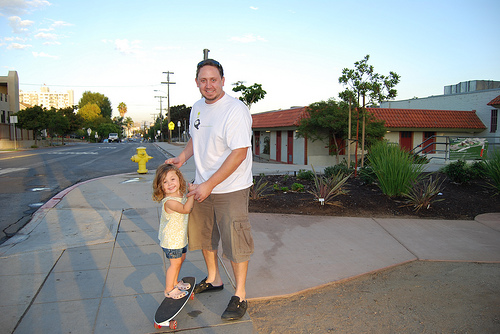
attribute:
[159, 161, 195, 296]
girl — little, standing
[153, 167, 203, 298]
girl — little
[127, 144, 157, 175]
fire hydrant — yellow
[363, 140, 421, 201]
plants — spike shaped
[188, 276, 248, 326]
shoes — black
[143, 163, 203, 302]
girl — little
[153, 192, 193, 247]
shirt — yellow, sleeveless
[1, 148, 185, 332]
sidewalk — sloped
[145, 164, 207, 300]
girl — little, standing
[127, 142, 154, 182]
hydrant — yellow, fire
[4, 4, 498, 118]
sky — sunny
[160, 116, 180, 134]
sign — yellow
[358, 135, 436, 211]
plants — green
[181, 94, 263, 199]
shirt — white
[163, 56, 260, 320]
man — holding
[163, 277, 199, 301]
shoes — croc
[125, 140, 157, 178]
hydrant — fire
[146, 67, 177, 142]
poles — electric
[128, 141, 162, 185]
hydrant — yellow, fire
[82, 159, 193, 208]
corner — street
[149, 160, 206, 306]
girl — little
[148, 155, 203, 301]
girl — little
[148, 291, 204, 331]
wheels — red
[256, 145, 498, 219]
landscaping — sparse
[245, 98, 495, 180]
building — red roofed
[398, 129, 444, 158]
doors — red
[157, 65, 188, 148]
pole — wooden, telephone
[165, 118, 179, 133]
sign — yellow, crossing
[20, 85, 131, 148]
trees — large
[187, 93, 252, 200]
shirt — white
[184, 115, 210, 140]
graphic — small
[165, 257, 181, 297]
leg — person's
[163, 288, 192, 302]
feet — person's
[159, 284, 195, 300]
feet — person's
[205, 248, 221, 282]
leg — person's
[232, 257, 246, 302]
leg — person's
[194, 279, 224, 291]
feet — person's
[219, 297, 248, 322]
feet — person's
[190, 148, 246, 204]
arm — person's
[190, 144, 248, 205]
arm — person's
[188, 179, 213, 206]
hand — person's